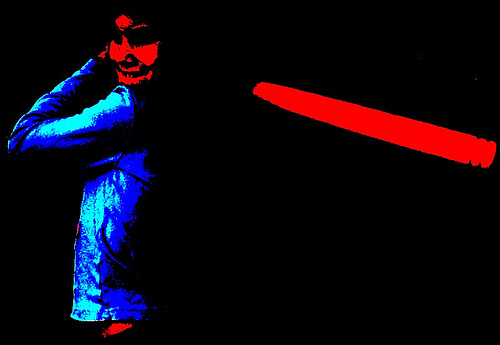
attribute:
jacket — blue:
[8, 58, 170, 325]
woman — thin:
[2, 4, 180, 339]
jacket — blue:
[6, 58, 155, 323]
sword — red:
[252, 80, 499, 171]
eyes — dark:
[100, 16, 162, 58]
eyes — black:
[102, 22, 167, 52]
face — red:
[99, 12, 184, 91]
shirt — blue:
[9, 72, 153, 320]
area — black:
[6, 6, 496, 337]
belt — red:
[58, 300, 154, 342]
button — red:
[68, 212, 83, 250]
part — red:
[95, 314, 136, 341]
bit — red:
[71, 220, 86, 237]